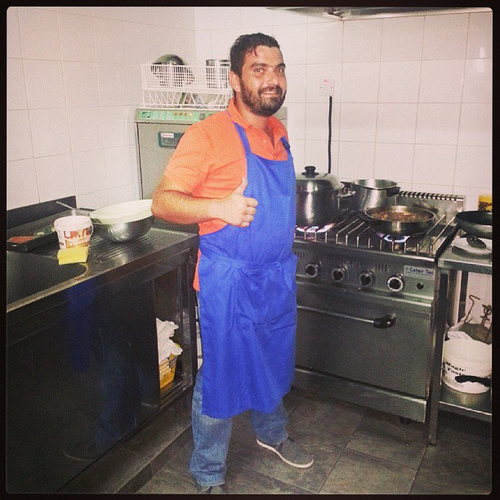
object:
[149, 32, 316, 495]
man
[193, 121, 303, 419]
apron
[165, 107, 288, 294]
shirt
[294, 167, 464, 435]
stove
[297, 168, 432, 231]
food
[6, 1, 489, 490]
kitchen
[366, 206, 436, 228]
frying pan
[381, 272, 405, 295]
knobs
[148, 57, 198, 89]
bowls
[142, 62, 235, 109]
rack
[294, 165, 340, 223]
pot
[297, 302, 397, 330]
handle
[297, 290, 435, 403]
oven door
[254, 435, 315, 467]
sneakers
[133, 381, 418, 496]
floor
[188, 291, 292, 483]
jeans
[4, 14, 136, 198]
tile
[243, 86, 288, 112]
beard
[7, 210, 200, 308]
sink